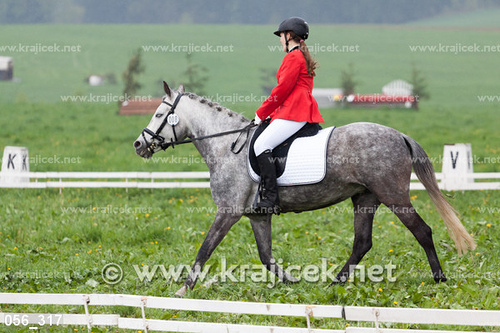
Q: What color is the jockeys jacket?
A: Red.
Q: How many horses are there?
A: One.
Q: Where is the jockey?
A: On the horse.